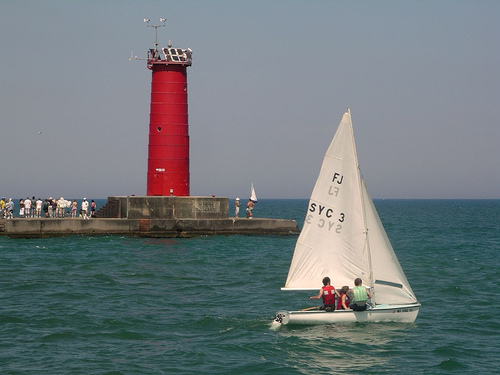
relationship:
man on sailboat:
[311, 277, 341, 314] [270, 109, 422, 330]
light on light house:
[142, 15, 165, 30] [147, 49, 190, 197]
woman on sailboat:
[337, 284, 352, 312] [270, 109, 422, 330]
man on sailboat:
[348, 277, 372, 311] [270, 109, 422, 330]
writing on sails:
[305, 171, 345, 232] [282, 109, 417, 305]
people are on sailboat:
[311, 277, 373, 310] [270, 109, 422, 330]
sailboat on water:
[270, 109, 422, 330] [1, 199, 499, 374]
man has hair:
[311, 277, 341, 314] [322, 277, 331, 285]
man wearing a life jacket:
[311, 277, 341, 314] [322, 284, 336, 306]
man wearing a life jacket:
[348, 277, 372, 311] [355, 286, 366, 303]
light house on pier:
[147, 49, 190, 197] [1, 197, 300, 237]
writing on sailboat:
[305, 171, 345, 232] [270, 109, 422, 330]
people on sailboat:
[311, 277, 373, 310] [270, 109, 422, 330]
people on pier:
[1, 196, 98, 219] [1, 197, 300, 237]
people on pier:
[233, 197, 254, 219] [1, 197, 300, 237]